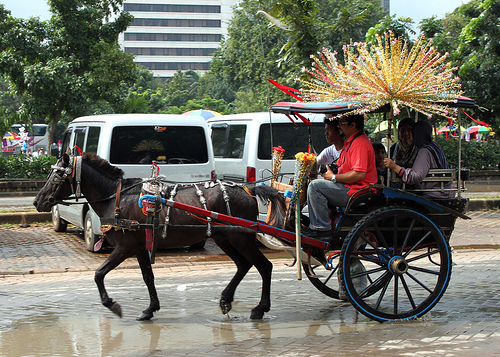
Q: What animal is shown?
A: HOrse.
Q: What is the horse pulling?
A: A carriage.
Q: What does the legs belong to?
A: A horse.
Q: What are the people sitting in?
A: A carriage.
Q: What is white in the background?
A: A building.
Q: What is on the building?
A: Windows.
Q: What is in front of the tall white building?
A: Trees.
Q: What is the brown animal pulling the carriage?
A: A horse.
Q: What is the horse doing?
A: Walking.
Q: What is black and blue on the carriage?
A: A wheel.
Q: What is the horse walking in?
A: Water.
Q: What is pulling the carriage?
A: Horses.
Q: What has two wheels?
A: A buggy.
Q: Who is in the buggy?
A: Man and women..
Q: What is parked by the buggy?
A: Two cars.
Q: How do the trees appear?
A: Lush.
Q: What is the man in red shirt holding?
A: Camera.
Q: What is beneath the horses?
A: Wet road.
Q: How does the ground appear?
A: Wet.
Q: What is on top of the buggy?
A: Decoration.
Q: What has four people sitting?
A: A buggy.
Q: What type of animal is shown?
A: Horse.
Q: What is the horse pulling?
A: A cart.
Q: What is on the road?
A: Water.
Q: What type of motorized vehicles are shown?
A: Vans.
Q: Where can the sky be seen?
A: Through the trees.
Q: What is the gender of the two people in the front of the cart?
A: Male.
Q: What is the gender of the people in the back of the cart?
A: Female.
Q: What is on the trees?
A: Green leaves.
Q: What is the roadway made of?
A: Cobblestone.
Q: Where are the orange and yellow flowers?
A: Between the men.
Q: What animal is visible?
A: Horse.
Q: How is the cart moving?
A: Pulled by a horse.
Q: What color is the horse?
A: Brown.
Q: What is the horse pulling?
A: Cart.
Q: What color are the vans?
A: White.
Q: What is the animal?
A: Horse.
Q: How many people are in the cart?
A: Five.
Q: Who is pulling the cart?
A: Horse.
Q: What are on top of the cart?
A: Flowers.